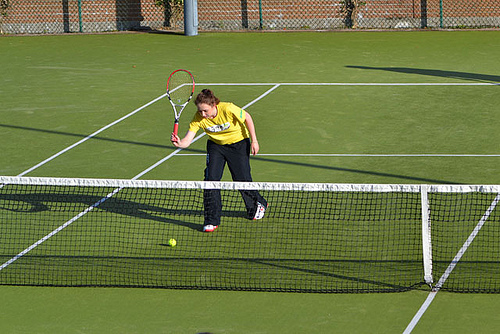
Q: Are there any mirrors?
A: No, there are no mirrors.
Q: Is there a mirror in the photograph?
A: No, there are no mirrors.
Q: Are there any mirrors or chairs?
A: No, there are no mirrors or chairs.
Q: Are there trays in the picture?
A: No, there are no trays.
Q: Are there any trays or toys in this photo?
A: No, there are no trays or toys.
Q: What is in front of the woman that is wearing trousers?
A: The net is in front of the woman.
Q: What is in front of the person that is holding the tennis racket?
A: The net is in front of the woman.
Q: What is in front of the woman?
A: The net is in front of the woman.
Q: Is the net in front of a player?
A: No, the net is in front of a woman.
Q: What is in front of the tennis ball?
A: The net is in front of the tennis ball.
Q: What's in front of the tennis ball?
A: The net is in front of the tennis ball.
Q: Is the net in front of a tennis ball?
A: Yes, the net is in front of a tennis ball.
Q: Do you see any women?
A: Yes, there is a woman.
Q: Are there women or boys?
A: Yes, there is a woman.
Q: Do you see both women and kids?
A: No, there is a woman but no children.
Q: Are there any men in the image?
A: No, there are no men.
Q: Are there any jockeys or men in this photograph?
A: No, there are no men or jockeys.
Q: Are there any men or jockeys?
A: No, there are no men or jockeys.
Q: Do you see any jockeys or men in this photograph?
A: No, there are no men or jockeys.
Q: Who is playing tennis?
A: The woman is playing tennis.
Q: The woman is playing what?
A: The woman is playing tennis.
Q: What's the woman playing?
A: The woman is playing tennis.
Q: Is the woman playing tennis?
A: Yes, the woman is playing tennis.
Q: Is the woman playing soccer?
A: No, the woman is playing tennis.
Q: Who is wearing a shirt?
A: The woman is wearing a shirt.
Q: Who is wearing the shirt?
A: The woman is wearing a shirt.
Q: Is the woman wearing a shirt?
A: Yes, the woman is wearing a shirt.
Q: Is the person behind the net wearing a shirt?
A: Yes, the woman is wearing a shirt.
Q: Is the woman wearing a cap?
A: No, the woman is wearing a shirt.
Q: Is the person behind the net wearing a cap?
A: No, the woman is wearing a shirt.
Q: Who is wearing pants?
A: The woman is wearing pants.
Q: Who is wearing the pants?
A: The woman is wearing pants.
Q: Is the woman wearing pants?
A: Yes, the woman is wearing pants.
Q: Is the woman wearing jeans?
A: No, the woman is wearing pants.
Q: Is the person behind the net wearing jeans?
A: No, the woman is wearing pants.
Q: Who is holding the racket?
A: The woman is holding the racket.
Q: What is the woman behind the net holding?
A: The woman is holding the tennis racket.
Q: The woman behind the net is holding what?
A: The woman is holding the tennis racket.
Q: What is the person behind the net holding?
A: The woman is holding the tennis racket.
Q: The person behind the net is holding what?
A: The woman is holding the tennis racket.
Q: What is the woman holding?
A: The woman is holding the tennis racket.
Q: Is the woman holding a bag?
A: No, the woman is holding the racket.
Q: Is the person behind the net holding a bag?
A: No, the woman is holding the racket.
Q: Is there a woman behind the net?
A: Yes, there is a woman behind the net.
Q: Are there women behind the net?
A: Yes, there is a woman behind the net.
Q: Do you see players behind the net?
A: No, there is a woman behind the net.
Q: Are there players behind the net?
A: No, there is a woman behind the net.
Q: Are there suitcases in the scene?
A: No, there are no suitcases.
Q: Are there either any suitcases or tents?
A: No, there are no suitcases or tents.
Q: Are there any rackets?
A: Yes, there is a racket.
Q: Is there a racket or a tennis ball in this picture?
A: Yes, there is a racket.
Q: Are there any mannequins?
A: No, there are no mannequins.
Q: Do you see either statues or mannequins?
A: No, there are no mannequins or statues.